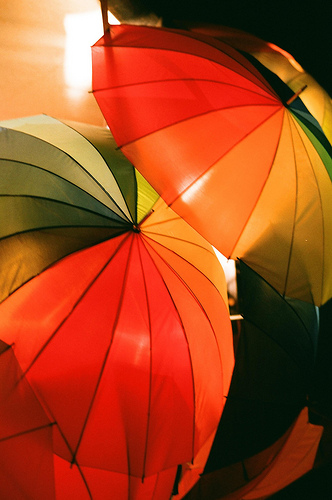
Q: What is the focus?
A: Umbrellas.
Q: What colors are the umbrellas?
A: Green, red, yellow, orange.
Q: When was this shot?
A: Night time.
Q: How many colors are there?
A: 4.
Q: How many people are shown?
A: 0.